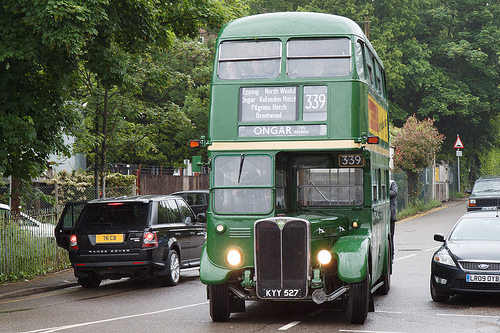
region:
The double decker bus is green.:
[202, 5, 396, 327]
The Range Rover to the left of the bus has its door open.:
[50, 190, 210, 292]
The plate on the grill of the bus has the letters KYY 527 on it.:
[261, 287, 303, 300]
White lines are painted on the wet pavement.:
[23, 235, 499, 330]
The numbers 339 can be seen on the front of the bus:
[300, 91, 361, 164]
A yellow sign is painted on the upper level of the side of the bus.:
[366, 93, 387, 144]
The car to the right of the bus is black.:
[427, 206, 497, 303]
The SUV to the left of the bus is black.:
[45, 191, 207, 293]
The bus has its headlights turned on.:
[215, 240, 336, 276]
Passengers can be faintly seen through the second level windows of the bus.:
[218, 39, 353, 83]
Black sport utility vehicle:
[53, 175, 193, 295]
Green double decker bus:
[196, 11, 408, 328]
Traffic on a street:
[51, 20, 498, 301]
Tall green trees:
[11, 10, 178, 152]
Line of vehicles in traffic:
[414, 172, 496, 287]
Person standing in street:
[383, 168, 403, 264]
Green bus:
[169, 5, 407, 326]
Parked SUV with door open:
[47, 177, 199, 294]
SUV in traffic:
[469, 172, 499, 208]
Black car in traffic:
[422, 200, 495, 311]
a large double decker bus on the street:
[11, 14, 465, 317]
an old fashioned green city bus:
[201, 21, 399, 328]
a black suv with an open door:
[52, 191, 205, 283]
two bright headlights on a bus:
[220, 232, 375, 281]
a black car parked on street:
[428, 212, 498, 317]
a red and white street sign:
[448, 131, 467, 206]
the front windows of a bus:
[219, 29, 360, 229]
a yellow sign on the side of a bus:
[364, 96, 394, 139]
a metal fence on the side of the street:
[6, 214, 66, 271]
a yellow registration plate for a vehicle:
[93, 232, 130, 248]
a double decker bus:
[197, 15, 409, 320]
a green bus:
[199, 7, 411, 329]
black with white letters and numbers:
[258, 284, 315, 306]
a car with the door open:
[48, 184, 198, 268]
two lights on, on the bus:
[202, 215, 351, 312]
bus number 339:
[333, 147, 370, 165]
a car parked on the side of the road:
[46, 179, 213, 290]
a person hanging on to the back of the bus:
[381, 161, 401, 278]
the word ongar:
[238, 121, 300, 138]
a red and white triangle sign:
[448, 133, 465, 150]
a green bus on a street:
[183, 3, 403, 325]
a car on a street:
[418, 202, 498, 322]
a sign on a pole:
[445, 128, 469, 164]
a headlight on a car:
[428, 249, 461, 276]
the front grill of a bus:
[247, 212, 317, 310]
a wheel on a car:
[160, 244, 185, 288]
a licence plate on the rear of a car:
[90, 227, 131, 259]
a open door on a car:
[41, 196, 96, 256]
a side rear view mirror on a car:
[426, 227, 456, 249]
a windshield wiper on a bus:
[231, 150, 248, 193]